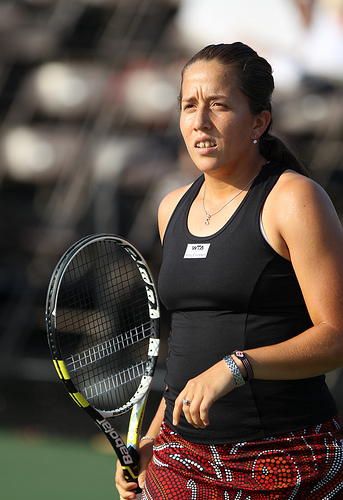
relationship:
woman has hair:
[115, 43, 342, 499] [177, 41, 311, 177]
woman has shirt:
[115, 43, 342, 499] [157, 165, 339, 444]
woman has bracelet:
[115, 43, 342, 499] [232, 348, 253, 384]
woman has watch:
[115, 43, 342, 499] [231, 351, 255, 384]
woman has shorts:
[115, 43, 342, 499] [142, 422, 341, 499]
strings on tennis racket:
[56, 240, 154, 410] [44, 235, 163, 497]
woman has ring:
[115, 43, 342, 499] [181, 398, 191, 406]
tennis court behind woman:
[0, 422, 145, 499] [115, 43, 342, 499]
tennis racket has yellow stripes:
[44, 235, 163, 497] [53, 358, 71, 381]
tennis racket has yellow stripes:
[44, 235, 163, 497] [66, 393, 91, 409]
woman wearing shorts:
[115, 43, 342, 499] [142, 422, 341, 499]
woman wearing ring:
[115, 43, 342, 499] [181, 398, 191, 406]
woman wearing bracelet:
[115, 43, 342, 499] [232, 348, 253, 384]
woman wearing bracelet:
[115, 43, 342, 499] [224, 355, 245, 387]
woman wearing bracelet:
[115, 43, 342, 499] [142, 435, 156, 443]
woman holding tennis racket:
[115, 43, 342, 499] [44, 235, 163, 497]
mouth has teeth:
[194, 139, 217, 151] [197, 142, 215, 147]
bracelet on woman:
[232, 348, 253, 384] [115, 43, 342, 499]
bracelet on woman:
[224, 355, 245, 387] [115, 43, 342, 499]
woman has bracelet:
[115, 43, 342, 499] [224, 355, 245, 387]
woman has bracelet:
[115, 43, 342, 499] [142, 435, 156, 443]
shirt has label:
[157, 165, 339, 444] [182, 244, 211, 257]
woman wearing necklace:
[115, 43, 342, 499] [201, 180, 253, 223]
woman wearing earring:
[115, 43, 342, 499] [253, 138, 260, 143]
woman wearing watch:
[115, 43, 342, 499] [231, 351, 255, 384]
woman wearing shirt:
[115, 43, 342, 499] [157, 165, 339, 444]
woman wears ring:
[115, 43, 342, 499] [181, 398, 191, 406]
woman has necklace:
[115, 43, 342, 499] [201, 180, 253, 223]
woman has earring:
[115, 43, 342, 499] [253, 138, 260, 143]